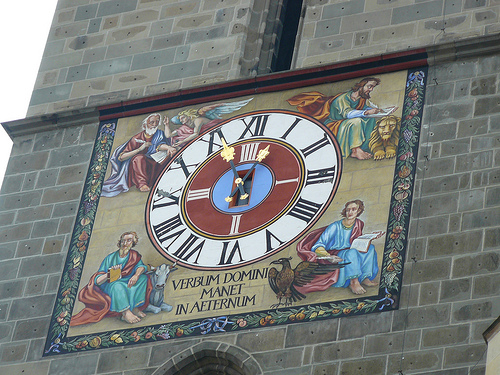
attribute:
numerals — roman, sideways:
[205, 117, 364, 187]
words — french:
[157, 270, 293, 336]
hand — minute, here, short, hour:
[206, 146, 239, 166]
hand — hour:
[235, 126, 286, 188]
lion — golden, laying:
[355, 118, 423, 184]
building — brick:
[69, 10, 213, 136]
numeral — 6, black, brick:
[199, 224, 269, 283]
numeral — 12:
[222, 101, 268, 138]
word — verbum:
[171, 262, 225, 291]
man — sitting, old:
[86, 225, 167, 299]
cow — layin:
[128, 232, 189, 324]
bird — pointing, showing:
[250, 246, 353, 283]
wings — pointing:
[300, 244, 342, 272]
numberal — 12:
[206, 98, 276, 157]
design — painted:
[62, 132, 105, 188]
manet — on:
[190, 274, 259, 304]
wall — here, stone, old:
[52, 75, 455, 283]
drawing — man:
[246, 237, 317, 307]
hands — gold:
[203, 109, 282, 183]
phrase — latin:
[176, 267, 366, 373]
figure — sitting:
[87, 109, 450, 368]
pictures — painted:
[121, 103, 356, 259]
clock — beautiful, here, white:
[144, 107, 342, 271]